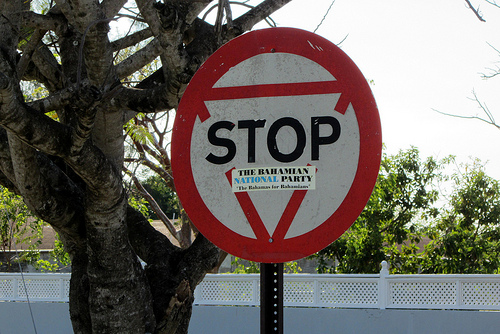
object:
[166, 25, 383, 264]
sign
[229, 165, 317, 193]
sticker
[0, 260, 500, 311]
fence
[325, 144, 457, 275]
trees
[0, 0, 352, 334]
trunk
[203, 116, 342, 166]
letters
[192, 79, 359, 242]
triangle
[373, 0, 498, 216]
sky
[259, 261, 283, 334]
post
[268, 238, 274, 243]
bolt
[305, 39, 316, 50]
scratch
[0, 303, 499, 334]
road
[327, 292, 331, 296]
holes